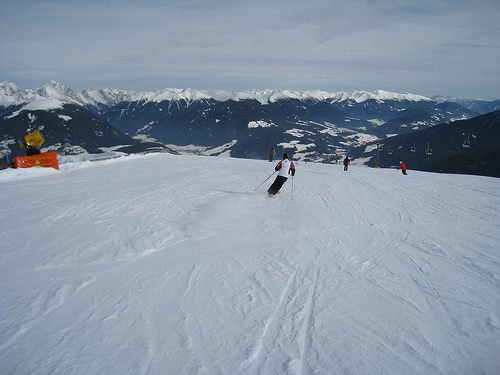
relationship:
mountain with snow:
[180, 85, 434, 149] [210, 187, 376, 311]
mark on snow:
[100, 191, 210, 271] [210, 187, 376, 311]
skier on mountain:
[249, 155, 308, 199] [180, 85, 434, 149]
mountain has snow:
[180, 85, 434, 149] [210, 187, 376, 311]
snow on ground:
[210, 187, 376, 311] [85, 185, 285, 276]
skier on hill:
[249, 155, 308, 199] [192, 133, 370, 189]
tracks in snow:
[44, 182, 163, 341] [210, 187, 376, 311]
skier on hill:
[249, 155, 308, 199] [129, 134, 473, 372]